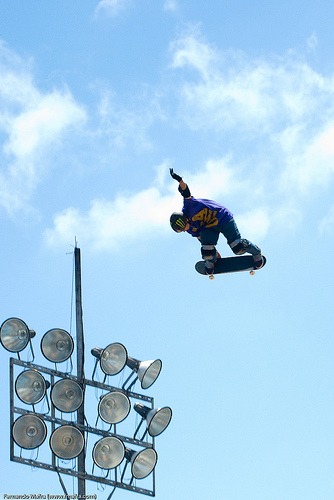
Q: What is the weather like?
A: It is clear.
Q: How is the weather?
A: It is clear.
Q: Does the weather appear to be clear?
A: Yes, it is clear.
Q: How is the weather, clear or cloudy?
A: It is clear.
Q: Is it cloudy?
A: No, it is clear.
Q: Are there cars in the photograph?
A: No, there are no cars.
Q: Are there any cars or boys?
A: No, there are no cars or boys.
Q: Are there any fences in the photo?
A: No, there are no fences.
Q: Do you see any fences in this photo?
A: No, there are no fences.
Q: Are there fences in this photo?
A: No, there are no fences.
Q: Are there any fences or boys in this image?
A: No, there are no fences or boys.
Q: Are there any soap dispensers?
A: No, there are no soap dispensers.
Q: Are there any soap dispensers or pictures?
A: No, there are no soap dispensers or pictures.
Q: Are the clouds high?
A: Yes, the clouds are high.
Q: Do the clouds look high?
A: Yes, the clouds are high.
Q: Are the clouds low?
A: No, the clouds are high.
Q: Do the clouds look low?
A: No, the clouds are high.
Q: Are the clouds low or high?
A: The clouds are high.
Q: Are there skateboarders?
A: Yes, there is a skateboarder.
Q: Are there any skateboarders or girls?
A: Yes, there is a skateboarder.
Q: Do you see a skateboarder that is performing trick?
A: Yes, there is a skateboarder that is performing trick.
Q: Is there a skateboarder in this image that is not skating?
A: Yes, there is a skateboarder that is performing trick.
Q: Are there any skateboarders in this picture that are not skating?
A: Yes, there is a skateboarder that is performing trick.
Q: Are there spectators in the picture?
A: No, there are no spectators.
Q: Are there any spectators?
A: No, there are no spectators.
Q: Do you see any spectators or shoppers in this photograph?
A: No, there are no spectators or shoppers.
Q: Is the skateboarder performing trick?
A: Yes, the skateboarder is performing trick.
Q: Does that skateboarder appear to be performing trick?
A: Yes, the skateboarder is performing trick.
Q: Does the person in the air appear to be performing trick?
A: Yes, the skateboarder is performing trick.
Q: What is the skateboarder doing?
A: The skateboarder is performing trick.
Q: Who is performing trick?
A: The skateboarder is performing trick.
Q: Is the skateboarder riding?
A: No, the skateboarder is performing trick.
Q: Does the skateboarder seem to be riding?
A: No, the skateboarder is performing trick.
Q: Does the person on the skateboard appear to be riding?
A: No, the skateboarder is performing trick.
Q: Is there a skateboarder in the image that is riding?
A: No, there is a skateboarder but he is performing trick.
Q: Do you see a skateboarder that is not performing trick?
A: No, there is a skateboarder but he is performing trick.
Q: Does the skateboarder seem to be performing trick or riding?
A: The skateboarder is performing trick.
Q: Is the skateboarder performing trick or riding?
A: The skateboarder is performing trick.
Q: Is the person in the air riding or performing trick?
A: The skateboarder is performing trick.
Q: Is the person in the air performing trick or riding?
A: The skateboarder is performing trick.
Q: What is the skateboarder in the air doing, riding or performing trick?
A: The skateboarder is performing trick.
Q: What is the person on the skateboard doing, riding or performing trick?
A: The skateboarder is performing trick.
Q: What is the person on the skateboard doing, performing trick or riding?
A: The skateboarder is performing trick.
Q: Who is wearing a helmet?
A: The skateboarder is wearing a helmet.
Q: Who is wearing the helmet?
A: The skateboarder is wearing a helmet.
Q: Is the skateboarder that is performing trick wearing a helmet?
A: Yes, the skateboarder is wearing a helmet.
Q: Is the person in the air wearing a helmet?
A: Yes, the skateboarder is wearing a helmet.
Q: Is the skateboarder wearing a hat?
A: No, the skateboarder is wearing a helmet.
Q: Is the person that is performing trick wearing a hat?
A: No, the skateboarder is wearing a helmet.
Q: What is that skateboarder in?
A: The skateboarder is in the air.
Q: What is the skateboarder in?
A: The skateboarder is in the air.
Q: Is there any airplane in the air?
A: No, there is a skateboarder in the air.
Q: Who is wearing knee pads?
A: The skateboarder is wearing knee pads.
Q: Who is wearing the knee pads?
A: The skateboarder is wearing knee pads.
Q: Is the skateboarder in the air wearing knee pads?
A: Yes, the skateboarder is wearing knee pads.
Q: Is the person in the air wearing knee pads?
A: Yes, the skateboarder is wearing knee pads.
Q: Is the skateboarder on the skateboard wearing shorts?
A: No, the skateboarder is wearing knee pads.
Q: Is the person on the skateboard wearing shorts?
A: No, the skateboarder is wearing knee pads.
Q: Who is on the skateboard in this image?
A: The skateboarder is on the skateboard.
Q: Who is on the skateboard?
A: The skateboarder is on the skateboard.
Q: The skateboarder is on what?
A: The skateboarder is on the skateboard.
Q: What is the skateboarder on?
A: The skateboarder is on the skateboard.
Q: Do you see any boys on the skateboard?
A: No, there is a skateboarder on the skateboard.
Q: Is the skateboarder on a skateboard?
A: Yes, the skateboarder is on a skateboard.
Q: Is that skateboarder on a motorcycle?
A: No, the skateboarder is on a skateboard.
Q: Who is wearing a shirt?
A: The skateboarder is wearing a shirt.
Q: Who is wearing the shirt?
A: The skateboarder is wearing a shirt.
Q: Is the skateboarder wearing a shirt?
A: Yes, the skateboarder is wearing a shirt.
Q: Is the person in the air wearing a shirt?
A: Yes, the skateboarder is wearing a shirt.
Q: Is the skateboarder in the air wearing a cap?
A: No, the skateboarder is wearing a shirt.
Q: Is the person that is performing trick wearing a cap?
A: No, the skateboarder is wearing a shirt.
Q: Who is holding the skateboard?
A: The skateboarder is holding the skateboard.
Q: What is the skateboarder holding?
A: The skateboarder is holding the skateboard.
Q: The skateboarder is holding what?
A: The skateboarder is holding the skateboard.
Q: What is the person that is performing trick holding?
A: The skateboarder is holding the skateboard.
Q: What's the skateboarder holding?
A: The skateboarder is holding the skateboard.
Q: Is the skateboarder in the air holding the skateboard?
A: Yes, the skateboarder is holding the skateboard.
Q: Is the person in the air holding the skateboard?
A: Yes, the skateboarder is holding the skateboard.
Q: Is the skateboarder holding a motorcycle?
A: No, the skateboarder is holding the skateboard.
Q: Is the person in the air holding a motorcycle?
A: No, the skateboarder is holding the skateboard.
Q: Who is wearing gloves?
A: The skateboarder is wearing gloves.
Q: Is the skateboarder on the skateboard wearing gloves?
A: Yes, the skateboarder is wearing gloves.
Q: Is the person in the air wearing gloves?
A: Yes, the skateboarder is wearing gloves.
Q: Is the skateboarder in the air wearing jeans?
A: No, the skateboarder is wearing gloves.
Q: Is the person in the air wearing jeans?
A: No, the skateboarder is wearing gloves.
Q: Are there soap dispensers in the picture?
A: No, there are no soap dispensers.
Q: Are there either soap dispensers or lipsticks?
A: No, there are no soap dispensers or lipsticks.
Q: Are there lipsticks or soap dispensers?
A: No, there are no soap dispensers or lipsticks.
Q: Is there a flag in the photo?
A: No, there are no flags.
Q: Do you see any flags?
A: No, there are no flags.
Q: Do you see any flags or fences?
A: No, there are no flags or fences.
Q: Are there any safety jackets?
A: No, there are no safety jackets.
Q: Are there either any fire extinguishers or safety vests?
A: No, there are no safety vests or fire extinguishers.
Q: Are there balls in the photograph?
A: No, there are no balls.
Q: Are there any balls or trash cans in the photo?
A: No, there are no balls or trash cans.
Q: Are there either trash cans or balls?
A: No, there are no balls or trash cans.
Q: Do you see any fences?
A: No, there are no fences.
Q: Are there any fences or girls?
A: No, there are no fences or girls.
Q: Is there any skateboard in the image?
A: Yes, there is a skateboard.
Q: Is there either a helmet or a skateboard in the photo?
A: Yes, there is a skateboard.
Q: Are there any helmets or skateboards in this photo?
A: Yes, there is a skateboard.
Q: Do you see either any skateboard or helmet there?
A: Yes, there is a skateboard.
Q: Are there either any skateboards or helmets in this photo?
A: Yes, there is a skateboard.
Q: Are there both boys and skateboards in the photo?
A: No, there is a skateboard but no boys.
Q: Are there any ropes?
A: No, there are no ropes.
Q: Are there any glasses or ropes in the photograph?
A: No, there are no ropes or glasses.